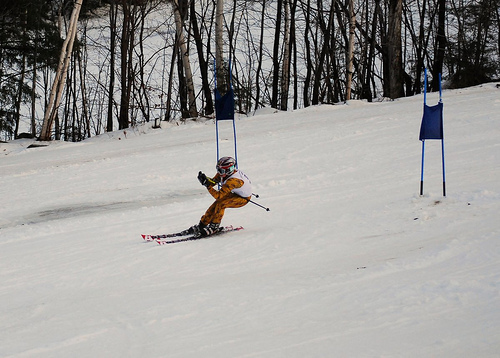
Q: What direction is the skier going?
A: Downhill.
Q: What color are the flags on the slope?
A: Blue.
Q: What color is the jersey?
A: White.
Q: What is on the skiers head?
A: A helmet.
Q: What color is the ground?
A: White.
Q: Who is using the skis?
A: The skier.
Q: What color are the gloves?
A: Black.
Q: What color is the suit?
A: Orange.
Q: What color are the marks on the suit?
A: Black.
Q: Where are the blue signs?
A: Behind the skier.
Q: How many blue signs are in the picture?
A: 2.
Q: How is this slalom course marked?
A: With blue flags.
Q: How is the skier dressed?
A: In an orange and black ski suit.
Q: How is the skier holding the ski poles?
A: Close to his body.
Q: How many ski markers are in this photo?
A: 2.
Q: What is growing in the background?
A: Trees.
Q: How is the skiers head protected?
A: With a helmet.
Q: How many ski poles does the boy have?
A: 2.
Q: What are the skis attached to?
A: The skiers boots.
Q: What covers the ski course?
A: Snow.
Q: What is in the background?
A: Trees.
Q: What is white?
A: Snow.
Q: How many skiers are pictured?
A: One.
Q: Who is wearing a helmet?
A: The skier.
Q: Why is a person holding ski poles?
A: To ski.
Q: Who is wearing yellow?
A: The skier.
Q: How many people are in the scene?
A: One.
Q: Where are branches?
A: On trees.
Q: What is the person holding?
A: Ski poles.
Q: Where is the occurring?
A: Downhill skiing track.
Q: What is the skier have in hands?
A: Ski poles.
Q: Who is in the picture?
A: One skier.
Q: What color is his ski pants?
A: Yellow.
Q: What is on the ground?
A: Snow.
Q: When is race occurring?
A: Winter.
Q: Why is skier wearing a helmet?
A: To prevent head injury.